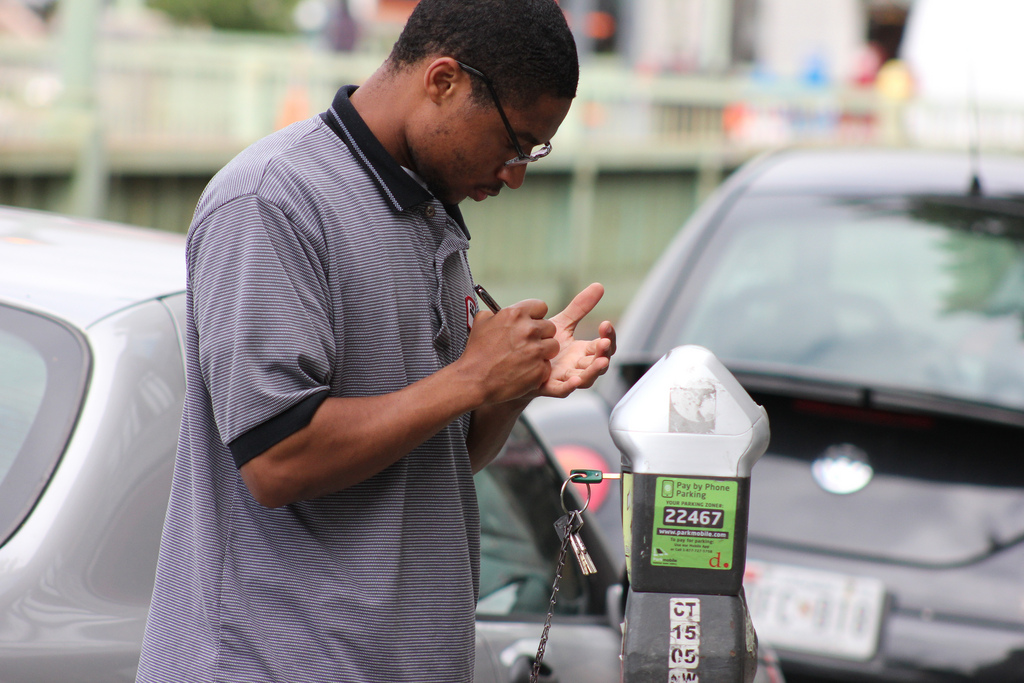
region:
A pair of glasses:
[444, 48, 563, 179]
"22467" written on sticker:
[652, 491, 729, 533]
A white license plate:
[727, 541, 895, 668]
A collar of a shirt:
[307, 65, 438, 225]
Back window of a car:
[645, 177, 1016, 419]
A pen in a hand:
[452, 269, 566, 418]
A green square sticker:
[637, 462, 742, 574]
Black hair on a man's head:
[371, 0, 588, 213]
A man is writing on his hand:
[177, 0, 624, 513]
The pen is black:
[463, 273, 515, 325]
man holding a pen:
[457, 288, 591, 384]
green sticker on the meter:
[641, 471, 740, 582]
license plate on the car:
[714, 544, 883, 656]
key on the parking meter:
[540, 451, 626, 505]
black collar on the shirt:
[332, 85, 440, 213]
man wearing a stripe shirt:
[133, 76, 538, 637]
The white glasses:
[445, 57, 573, 174]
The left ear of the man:
[412, 51, 476, 109]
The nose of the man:
[495, 156, 538, 189]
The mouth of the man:
[466, 174, 504, 209]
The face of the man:
[340, 1, 590, 198]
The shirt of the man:
[183, 126, 542, 680]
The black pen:
[461, 276, 522, 315]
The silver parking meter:
[520, 325, 819, 680]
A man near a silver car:
[138, 0, 630, 674]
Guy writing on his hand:
[130, 9, 615, 680]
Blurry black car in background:
[588, 141, 1015, 680]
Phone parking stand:
[607, 344, 769, 678]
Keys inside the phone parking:
[553, 467, 621, 576]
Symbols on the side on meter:
[667, 594, 702, 678]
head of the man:
[290, 10, 627, 217]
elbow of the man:
[198, 408, 391, 541]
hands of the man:
[403, 252, 642, 452]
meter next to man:
[562, 307, 820, 666]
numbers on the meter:
[640, 483, 748, 551]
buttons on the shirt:
[378, 179, 505, 375]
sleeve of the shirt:
[157, 164, 393, 500]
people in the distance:
[657, 6, 932, 142]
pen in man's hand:
[458, 263, 519, 336]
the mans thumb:
[554, 260, 600, 325]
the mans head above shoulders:
[346, 0, 581, 216]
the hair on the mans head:
[392, 0, 580, 103]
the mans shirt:
[117, 73, 498, 680]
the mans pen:
[466, 279, 517, 327]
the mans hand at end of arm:
[443, 287, 555, 420]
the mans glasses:
[465, 59, 557, 174]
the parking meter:
[596, 332, 775, 672]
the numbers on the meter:
[655, 498, 726, 527]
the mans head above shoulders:
[351, 0, 604, 206]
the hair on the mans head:
[428, 1, 574, 74]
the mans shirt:
[121, 79, 526, 677]